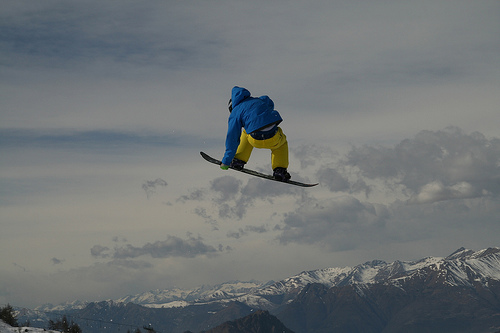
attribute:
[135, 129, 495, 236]
clouds — white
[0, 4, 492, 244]
sky — blue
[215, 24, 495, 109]
cloud — white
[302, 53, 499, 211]
clouds — white 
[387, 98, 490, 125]
clouds — white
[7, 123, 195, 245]
sky — blue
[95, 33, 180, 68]
white clouds — fluffy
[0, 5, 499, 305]
blue sky — large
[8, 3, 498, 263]
clouds — white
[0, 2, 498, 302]
sky — blue